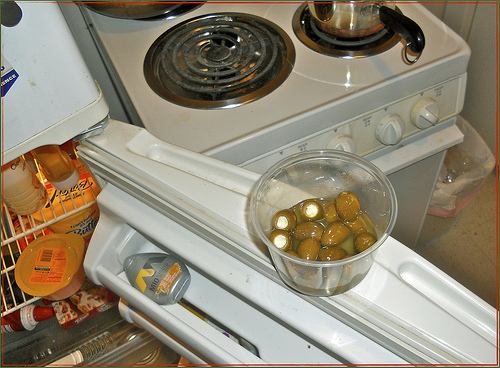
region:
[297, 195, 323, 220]
Cheese stuffed olive in container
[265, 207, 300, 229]
Cheese stuffed olive in container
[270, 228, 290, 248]
Cheese stuffed olive in container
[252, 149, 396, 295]
Round plastic container on fridge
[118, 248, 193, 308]
Gatorade energy drink in fridge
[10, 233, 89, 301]
Ham on shelf of fridge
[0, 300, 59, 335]
Whip cream bottle in fridge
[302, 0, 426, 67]
Pot on white stove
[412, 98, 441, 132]
White button on white stove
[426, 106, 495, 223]
Plastic trash bag next to white stove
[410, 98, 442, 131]
a knob on the stove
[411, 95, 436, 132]
a white knob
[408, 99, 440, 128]
a white knob on the stove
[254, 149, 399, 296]
a clear container filled with stuffed olives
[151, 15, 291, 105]
the large burner on the stove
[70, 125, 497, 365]
a refrigerator door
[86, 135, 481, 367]
a white refrigerator door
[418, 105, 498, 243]
a trash can next to the stove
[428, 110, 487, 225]
a plastic trash bag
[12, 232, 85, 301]
lunch meat in the refridgerator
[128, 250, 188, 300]
Gray and yellow container in refrigerator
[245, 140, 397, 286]
clear plastic container of food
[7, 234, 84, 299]
Yellow plastic top of package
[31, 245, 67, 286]
Orange ingredient label on package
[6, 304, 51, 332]
Horizontal can of whipped cream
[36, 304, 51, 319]
Long red lid of whipped cream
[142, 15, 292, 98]
Electric stove metal coils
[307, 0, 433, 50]
Silver saucepan on stove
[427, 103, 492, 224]
Trash can beside stove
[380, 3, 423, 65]
Black pan handle with silver ring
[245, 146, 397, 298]
a plastic container with stuffed olives and liquid inside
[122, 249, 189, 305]
a bottle of MIO water flavorer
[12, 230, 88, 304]
a package of bologna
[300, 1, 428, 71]
a sauce pan with black handle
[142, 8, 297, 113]
an electric burner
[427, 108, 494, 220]
a garbage can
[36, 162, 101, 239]
a plastic container of I Can't Believe It's Not Butter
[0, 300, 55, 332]
a can of whipped cream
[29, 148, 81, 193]
a mustard bottle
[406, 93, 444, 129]
a white handle to control an electric burner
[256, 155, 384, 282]
cup of green olives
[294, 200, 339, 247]
green olives in liquid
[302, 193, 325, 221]
white cheese inside green olive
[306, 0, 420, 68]
pot on top of stove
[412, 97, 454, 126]
white stove knob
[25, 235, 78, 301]
container of sandwich meat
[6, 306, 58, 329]
container of whip cream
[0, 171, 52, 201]
container of coffee sweetner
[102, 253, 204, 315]
silver bottle on side of fridge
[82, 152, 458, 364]
open fridge door on unit